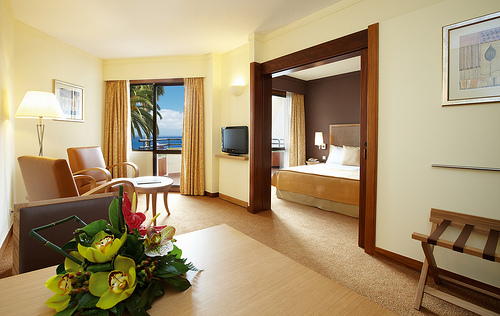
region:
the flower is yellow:
[31, 119, 156, 308]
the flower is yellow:
[92, 175, 217, 298]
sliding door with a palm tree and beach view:
[106, 80, 203, 190]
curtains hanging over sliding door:
[105, 80, 205, 195]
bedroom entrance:
[249, 20, 379, 247]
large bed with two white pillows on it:
[271, 140, 361, 220]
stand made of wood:
[409, 206, 499, 311]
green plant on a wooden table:
[1, 184, 402, 314]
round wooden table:
[131, 169, 178, 224]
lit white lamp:
[11, 88, 69, 154]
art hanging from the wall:
[48, 76, 90, 121]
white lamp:
[313, 132, 325, 149]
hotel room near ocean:
[0, 0, 498, 315]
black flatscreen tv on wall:
[216, 123, 249, 158]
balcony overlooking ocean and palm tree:
[129, 77, 184, 192]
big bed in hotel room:
[275, 107, 364, 219]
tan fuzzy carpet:
[127, 187, 499, 314]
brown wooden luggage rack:
[405, 207, 499, 314]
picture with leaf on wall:
[438, 17, 498, 110]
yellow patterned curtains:
[103, 76, 205, 193]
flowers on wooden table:
[0, 203, 405, 313]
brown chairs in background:
[19, 136, 140, 217]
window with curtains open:
[104, 74, 208, 177]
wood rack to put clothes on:
[412, 199, 494, 309]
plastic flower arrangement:
[28, 197, 193, 308]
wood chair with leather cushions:
[72, 140, 137, 199]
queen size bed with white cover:
[285, 115, 355, 210]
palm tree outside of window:
[128, 86, 159, 141]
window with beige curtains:
[102, 72, 214, 193]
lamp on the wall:
[312, 121, 329, 153]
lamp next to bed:
[308, 122, 325, 159]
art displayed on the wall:
[439, 18, 499, 103]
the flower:
[43, 168, 186, 313]